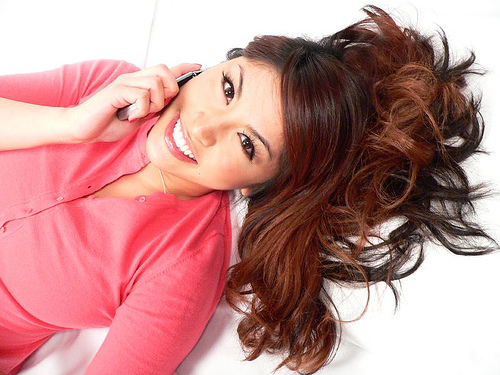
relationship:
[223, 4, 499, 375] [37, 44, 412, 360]
hair on woman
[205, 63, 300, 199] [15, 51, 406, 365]
eyes on woman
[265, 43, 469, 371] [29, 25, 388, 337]
hair on woman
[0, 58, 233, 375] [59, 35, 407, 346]
shirt on woman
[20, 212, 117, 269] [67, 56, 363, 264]
shirt on woman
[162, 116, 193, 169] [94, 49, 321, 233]
lipstick on woman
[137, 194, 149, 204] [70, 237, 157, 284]
button on sweater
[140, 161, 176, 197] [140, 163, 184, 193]
necklace on neck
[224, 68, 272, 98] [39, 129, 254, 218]
eyebrow on woman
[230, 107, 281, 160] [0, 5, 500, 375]
eyebrow on lady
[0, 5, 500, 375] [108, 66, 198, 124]
lady talking phone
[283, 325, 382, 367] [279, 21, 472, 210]
shadow from hair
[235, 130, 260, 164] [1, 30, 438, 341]
eyes of a woman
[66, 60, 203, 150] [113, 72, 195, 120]
hand holding phone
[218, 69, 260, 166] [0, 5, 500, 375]
eyes of lady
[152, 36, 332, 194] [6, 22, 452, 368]
head of woman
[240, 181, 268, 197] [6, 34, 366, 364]
ear of girl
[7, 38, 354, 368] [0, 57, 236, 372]
lady wearing shirt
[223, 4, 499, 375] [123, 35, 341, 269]
hair on a woman